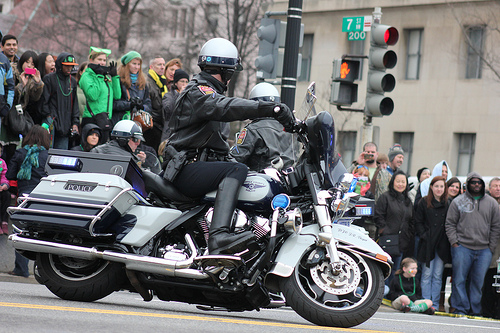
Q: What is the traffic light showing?
A: A red light.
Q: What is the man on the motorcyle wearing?
A: A helmet.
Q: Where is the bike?
A: On the street.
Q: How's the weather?
A: Cloudy and cold.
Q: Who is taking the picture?
A: A pedestrian.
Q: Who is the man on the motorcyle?
A: A policeman.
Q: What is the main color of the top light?
A: Red.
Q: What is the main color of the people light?
A: Red.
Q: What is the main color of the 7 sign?
A: Green.